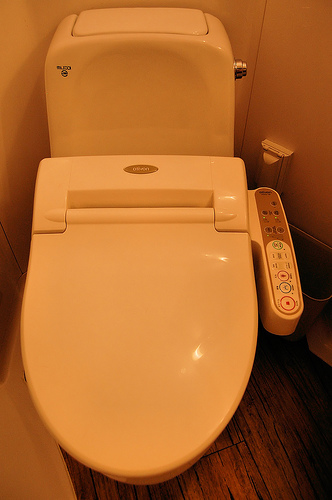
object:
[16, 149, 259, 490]
seat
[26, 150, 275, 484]
toilet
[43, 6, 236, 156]
toilet tank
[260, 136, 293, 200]
outlet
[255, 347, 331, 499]
floor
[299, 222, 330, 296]
waste basket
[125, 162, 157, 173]
emblem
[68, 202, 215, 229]
hinge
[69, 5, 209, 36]
opening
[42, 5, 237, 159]
tank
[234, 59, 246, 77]
chrome button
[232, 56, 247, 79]
flusher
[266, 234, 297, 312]
buttons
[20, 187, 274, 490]
lid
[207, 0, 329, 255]
wall